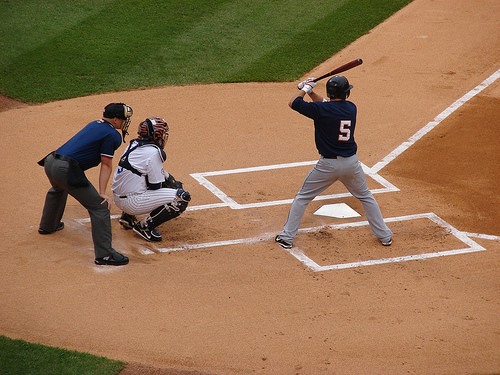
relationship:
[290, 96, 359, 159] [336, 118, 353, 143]
jersey has number 5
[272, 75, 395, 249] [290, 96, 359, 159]
batter wearing jersey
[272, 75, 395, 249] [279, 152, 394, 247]
batter wearing pants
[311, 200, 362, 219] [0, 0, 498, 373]
home plate on baseball field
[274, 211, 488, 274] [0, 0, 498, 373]
batter's box on baseball field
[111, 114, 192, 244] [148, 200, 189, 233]
catcher has shin guard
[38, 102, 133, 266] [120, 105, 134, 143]
man has face protection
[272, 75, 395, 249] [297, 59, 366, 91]
batter has baseball bat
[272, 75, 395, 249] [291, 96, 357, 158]
batter has jersey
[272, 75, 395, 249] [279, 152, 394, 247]
batter has pants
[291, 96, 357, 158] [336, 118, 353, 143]
jersey has 5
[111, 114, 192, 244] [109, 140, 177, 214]
catcher has clothes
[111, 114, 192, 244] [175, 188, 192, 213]
catcher wearing knee pads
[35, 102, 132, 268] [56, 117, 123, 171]
man has shirt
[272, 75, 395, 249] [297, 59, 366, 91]
baseball player with baseball bat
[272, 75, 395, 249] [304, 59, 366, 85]
person holding baseball bat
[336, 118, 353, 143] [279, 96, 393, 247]
5 on uniform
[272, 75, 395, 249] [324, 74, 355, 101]
person wearing helmet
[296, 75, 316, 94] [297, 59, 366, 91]
hands holding baseball bat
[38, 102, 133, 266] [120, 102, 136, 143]
man wearing face protection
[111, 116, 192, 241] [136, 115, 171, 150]
catcher wearing face protection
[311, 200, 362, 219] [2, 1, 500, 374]
home plate on ground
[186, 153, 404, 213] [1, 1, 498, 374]
batter's box on baseball field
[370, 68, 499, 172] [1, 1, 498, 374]
foul line on baseball field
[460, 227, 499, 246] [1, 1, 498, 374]
foul line on baseball field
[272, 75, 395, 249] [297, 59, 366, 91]
batter with baseball bat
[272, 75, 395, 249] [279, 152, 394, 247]
batter in pants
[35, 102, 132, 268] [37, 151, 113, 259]
man in pants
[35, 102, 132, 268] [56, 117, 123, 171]
man in shirt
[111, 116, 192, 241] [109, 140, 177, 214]
catcher in white